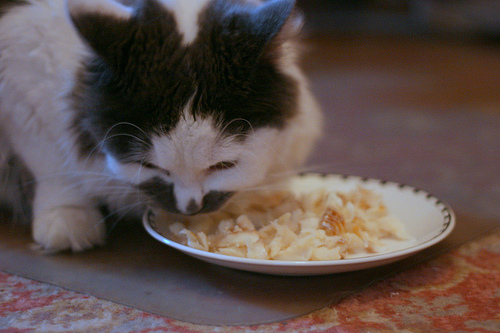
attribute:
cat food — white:
[167, 184, 412, 259]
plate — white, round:
[142, 171, 455, 277]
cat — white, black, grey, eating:
[0, 0, 325, 252]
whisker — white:
[82, 121, 158, 164]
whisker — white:
[211, 115, 258, 146]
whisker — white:
[97, 193, 163, 239]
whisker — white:
[10, 173, 120, 194]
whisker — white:
[213, 153, 262, 191]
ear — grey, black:
[210, 0, 298, 83]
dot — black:
[186, 196, 200, 216]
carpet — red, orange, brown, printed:
[0, 0, 499, 333]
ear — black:
[65, 0, 154, 73]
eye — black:
[140, 162, 159, 173]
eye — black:
[209, 157, 238, 171]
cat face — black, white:
[90, 1, 293, 215]